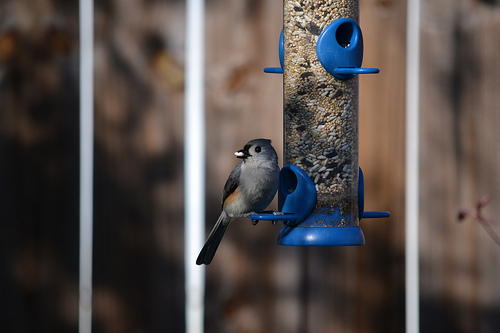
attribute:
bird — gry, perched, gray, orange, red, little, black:
[196, 138, 283, 265]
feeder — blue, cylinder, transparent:
[252, 0, 394, 246]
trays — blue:
[247, 15, 392, 228]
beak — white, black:
[234, 145, 250, 159]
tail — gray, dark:
[196, 212, 226, 267]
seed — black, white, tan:
[284, 0, 359, 222]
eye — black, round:
[253, 145, 262, 154]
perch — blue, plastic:
[249, 212, 297, 222]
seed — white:
[234, 152, 246, 156]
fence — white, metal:
[78, 0, 422, 331]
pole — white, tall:
[79, 1, 93, 331]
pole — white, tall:
[186, 0, 204, 331]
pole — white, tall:
[406, 0, 421, 331]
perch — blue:
[334, 67, 383, 75]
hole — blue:
[335, 22, 360, 50]